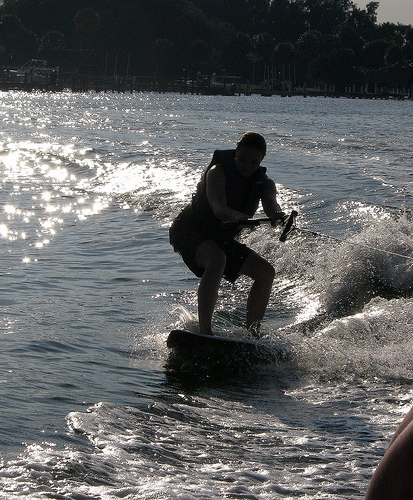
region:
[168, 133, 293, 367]
wakesurfer being pulled by a boat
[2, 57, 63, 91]
boats docked at a wood dock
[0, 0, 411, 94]
large trees at the shoreline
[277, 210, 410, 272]
the boats ski tow line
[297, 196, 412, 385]
the wake from the boat engine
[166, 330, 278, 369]
a surfboard being pulled behind a boat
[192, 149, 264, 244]
a surfer is wearing a life vest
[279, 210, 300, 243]
the handle of the water skiing tow line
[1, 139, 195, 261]
the water is reflecting the sun light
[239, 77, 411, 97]
the wood dock pilings of a dock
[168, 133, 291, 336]
the man is surfing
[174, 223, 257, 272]
the man is wearing black shorts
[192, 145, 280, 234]
the man is wearing a black life jacket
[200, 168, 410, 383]
this part of the sea has waves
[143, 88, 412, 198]
this part of the sea is calm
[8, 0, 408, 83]
there are trees in the background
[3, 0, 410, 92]
the trees in the background are green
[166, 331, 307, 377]
this is the surf the man is using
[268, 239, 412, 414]
the water looks white in color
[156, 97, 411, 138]
the water looks blue in color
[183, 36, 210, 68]
a tree in a distance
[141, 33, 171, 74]
a tree in a distance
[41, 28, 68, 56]
a tree in a distance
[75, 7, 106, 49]
a tree in a distance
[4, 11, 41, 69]
a tree in a distance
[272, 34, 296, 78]
a tree in a distance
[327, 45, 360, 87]
a tree in a distance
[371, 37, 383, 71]
a tree in a distance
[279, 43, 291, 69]
a tree in a distance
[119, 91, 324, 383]
a person surfing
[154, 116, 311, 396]
the woman is surfing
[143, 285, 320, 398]
the surfboard is blue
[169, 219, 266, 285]
woman is wearing shorts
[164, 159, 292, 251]
the vest is black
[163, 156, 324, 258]
woman is wearing a vest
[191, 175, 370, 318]
the woman is holding on a pole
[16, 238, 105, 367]
the water is blue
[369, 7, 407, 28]
the sky is gray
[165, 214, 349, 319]
the shorts are black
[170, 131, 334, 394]
the woman is on the water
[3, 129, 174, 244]
Sunlight is reflecting off the water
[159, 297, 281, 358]
Woman is surfing on board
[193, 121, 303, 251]
Woman has a life jacket on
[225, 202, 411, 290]
Woman is being pulled behind to be able to go faster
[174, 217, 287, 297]
Woman is bending her knees to hold her balance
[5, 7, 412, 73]
Trees in background are green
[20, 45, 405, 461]
Season is summer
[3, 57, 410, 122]
There are wooden docks in the background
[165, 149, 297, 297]
Woman is wearing swim trunks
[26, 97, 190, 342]
Water is blue